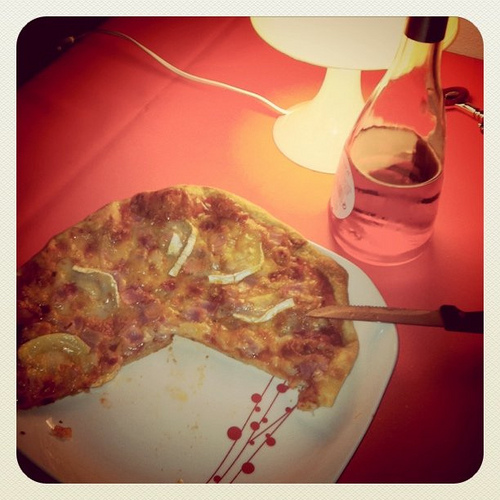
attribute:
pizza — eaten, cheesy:
[22, 183, 359, 409]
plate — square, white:
[17, 413, 375, 481]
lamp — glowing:
[248, 17, 336, 174]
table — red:
[23, 20, 250, 182]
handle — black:
[438, 305, 485, 333]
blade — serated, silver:
[306, 305, 442, 326]